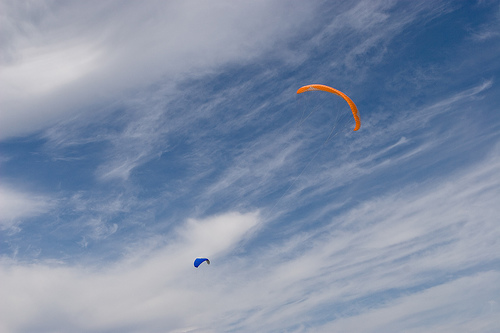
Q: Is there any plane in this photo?
A: No, there are no airplanes.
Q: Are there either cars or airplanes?
A: No, there are no airplanes or cars.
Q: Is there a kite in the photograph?
A: Yes, there is a kite.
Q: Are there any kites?
A: Yes, there is a kite.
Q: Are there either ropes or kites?
A: Yes, there is a kite.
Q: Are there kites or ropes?
A: Yes, there is a kite.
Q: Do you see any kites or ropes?
A: Yes, there is a kite.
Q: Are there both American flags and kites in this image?
A: No, there is a kite but no American flags.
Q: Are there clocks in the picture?
A: No, there are no clocks.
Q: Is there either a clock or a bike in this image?
A: No, there are no clocks or bikes.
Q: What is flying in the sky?
A: The kite is flying in the sky.